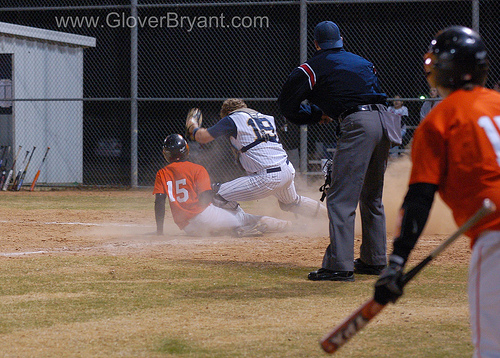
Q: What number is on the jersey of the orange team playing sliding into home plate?
A: Fifteen.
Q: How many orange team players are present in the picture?
A: Two.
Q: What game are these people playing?
A: Baseball.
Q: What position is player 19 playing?
A: Catcher.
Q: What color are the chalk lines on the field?
A: White.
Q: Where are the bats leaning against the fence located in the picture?
A: Left.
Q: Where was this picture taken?
A: Baseball field.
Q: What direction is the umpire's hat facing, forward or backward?
A: Backward.